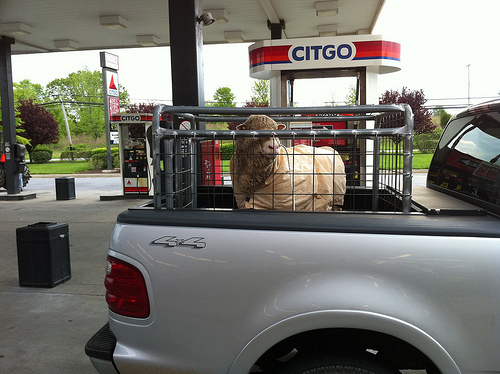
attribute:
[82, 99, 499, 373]
pickup — four by four, gray, silver, fueling up, white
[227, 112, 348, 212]
sheep — clothed, waiting, alone, large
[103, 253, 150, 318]
taillight — red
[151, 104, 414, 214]
cage — silver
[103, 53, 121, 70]
board — white, red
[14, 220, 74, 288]
trash can — black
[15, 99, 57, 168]
tree — beautifull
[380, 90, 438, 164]
tree — beautifull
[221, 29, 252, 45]
light — outdoor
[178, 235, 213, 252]
number — black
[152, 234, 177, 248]
number — black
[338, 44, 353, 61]
letter — blue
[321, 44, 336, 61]
letter — blue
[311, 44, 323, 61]
letter — blue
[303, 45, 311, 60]
letter — blue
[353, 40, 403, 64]
lines — red